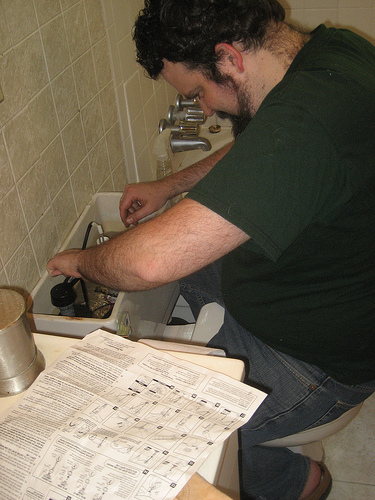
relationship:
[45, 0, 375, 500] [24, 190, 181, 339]
guy repairing a bowl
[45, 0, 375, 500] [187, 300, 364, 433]
guy sitting on toilet seat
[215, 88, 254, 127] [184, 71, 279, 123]
beard on chin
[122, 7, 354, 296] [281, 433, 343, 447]
guy seated on toilet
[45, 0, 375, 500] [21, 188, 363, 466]
guy fixing toilet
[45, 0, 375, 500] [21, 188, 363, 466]
guy sitting on toilet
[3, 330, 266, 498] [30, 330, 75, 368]
instruction manual on sink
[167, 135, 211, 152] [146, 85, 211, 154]
faucet attached to wall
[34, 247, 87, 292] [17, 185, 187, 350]
hand in bowl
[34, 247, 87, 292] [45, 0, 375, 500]
hand on guy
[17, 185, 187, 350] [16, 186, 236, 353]
bowl on toilet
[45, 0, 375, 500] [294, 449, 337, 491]
guy wearing sandals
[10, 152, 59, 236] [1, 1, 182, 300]
tile on tiled wall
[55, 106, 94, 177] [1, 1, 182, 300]
tile on tiled wall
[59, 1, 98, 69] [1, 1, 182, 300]
tile on tiled wall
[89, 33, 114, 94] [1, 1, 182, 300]
tile on tiled wall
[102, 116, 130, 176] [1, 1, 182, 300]
tile on tiled wall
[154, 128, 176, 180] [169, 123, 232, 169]
bottle on tub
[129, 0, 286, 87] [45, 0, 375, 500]
hair on guy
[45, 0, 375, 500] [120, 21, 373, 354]
guy wearing shirt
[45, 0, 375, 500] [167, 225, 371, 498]
guy wearing blue jeans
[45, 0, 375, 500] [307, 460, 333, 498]
guy wearing sandals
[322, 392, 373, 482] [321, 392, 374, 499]
tile on floor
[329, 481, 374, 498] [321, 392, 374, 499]
tile on floor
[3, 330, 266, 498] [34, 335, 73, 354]
instruction manual on sink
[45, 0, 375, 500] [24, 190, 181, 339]
guy working on bowl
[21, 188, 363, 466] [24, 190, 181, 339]
toilet on bowl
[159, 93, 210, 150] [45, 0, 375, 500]
faucet behind guy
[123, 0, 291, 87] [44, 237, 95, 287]
hair on hand